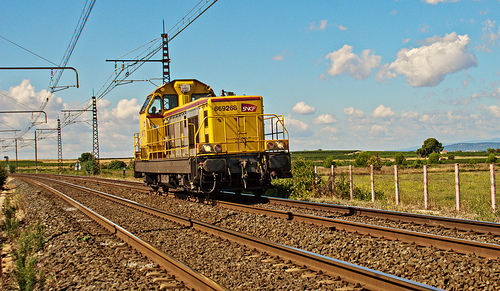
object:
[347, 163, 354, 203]
fence post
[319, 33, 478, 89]
cumulus clouds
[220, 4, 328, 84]
blue sky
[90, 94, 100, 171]
post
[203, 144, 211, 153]
headlights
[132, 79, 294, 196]
headlights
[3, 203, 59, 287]
weeds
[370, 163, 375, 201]
post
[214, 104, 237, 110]
numbers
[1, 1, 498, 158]
sky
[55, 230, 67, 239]
rock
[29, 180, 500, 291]
brown rocks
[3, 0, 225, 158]
cables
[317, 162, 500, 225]
meadow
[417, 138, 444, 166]
tree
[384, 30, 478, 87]
clouds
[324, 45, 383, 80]
clouds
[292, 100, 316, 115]
clouds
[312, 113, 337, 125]
clouds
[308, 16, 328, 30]
clouds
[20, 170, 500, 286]
rail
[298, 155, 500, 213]
fence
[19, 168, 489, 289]
ground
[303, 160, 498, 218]
wooden fence